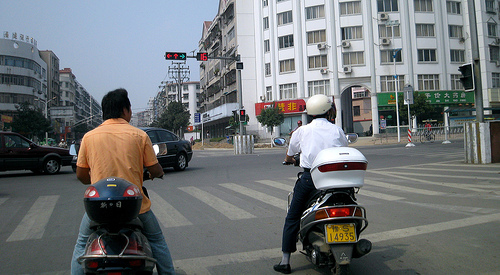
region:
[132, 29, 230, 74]
the traffic light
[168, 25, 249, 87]
the traffic light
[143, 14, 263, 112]
the traffic light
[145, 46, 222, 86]
the traffic light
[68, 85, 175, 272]
man on left riding a moped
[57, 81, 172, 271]
man wearing an orange shirt riding a moped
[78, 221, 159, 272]
back of moped the man with the orange shirt is riding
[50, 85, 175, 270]
man in blue jeans and orange shirt riding a moped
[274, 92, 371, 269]
person on the right side of the road riding a moped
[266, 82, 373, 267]
person in white shirt and white helmet riding moped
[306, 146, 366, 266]
moped that the person in the white shirt is riding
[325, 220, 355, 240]
license plate of moped the person in white shirt is riding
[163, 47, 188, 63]
traffic light cautioning the moped riders to stop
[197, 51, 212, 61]
lighted numbers of 16 beside the caution light on a utility pole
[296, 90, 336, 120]
hard white motorcycle helmet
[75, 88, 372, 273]
two men on motor scooters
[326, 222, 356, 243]
yellow license plate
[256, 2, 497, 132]
white building on the corner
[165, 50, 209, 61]
traffic lights over the intersection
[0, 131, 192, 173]
two cars in the intersection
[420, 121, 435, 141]
person riding a bike across the street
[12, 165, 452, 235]
white lines of the crosswalk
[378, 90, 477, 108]
green sign on white building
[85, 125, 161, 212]
orange shirt on biker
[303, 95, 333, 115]
white motorcycle helmet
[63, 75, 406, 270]
two mean riding motorcycles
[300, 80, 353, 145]
a man wearing a white helmet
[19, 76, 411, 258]
two motorcycle riders stopped at a traffic light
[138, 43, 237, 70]
a traffic light on a pole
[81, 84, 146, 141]
a man with black hair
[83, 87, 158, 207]
a man wearing a orange shirt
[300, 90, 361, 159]
a man wearing a white shirt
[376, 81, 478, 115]
green and white street signs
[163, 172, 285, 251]
white lines painted on a road way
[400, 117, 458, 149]
a metal bike rack